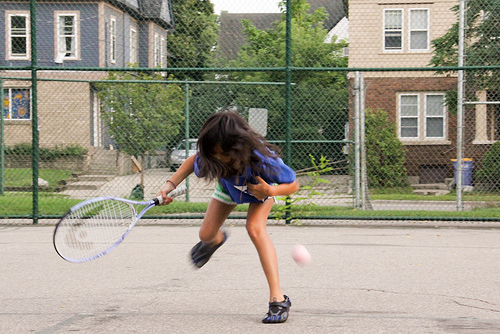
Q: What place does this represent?
A: It represents the pavement.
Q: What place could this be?
A: It is a pavement.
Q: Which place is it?
A: It is a pavement.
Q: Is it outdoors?
A: Yes, it is outdoors.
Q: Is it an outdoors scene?
A: Yes, it is outdoors.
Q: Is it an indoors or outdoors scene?
A: It is outdoors.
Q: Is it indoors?
A: No, it is outdoors.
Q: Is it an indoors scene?
A: No, it is outdoors.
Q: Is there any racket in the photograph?
A: Yes, there is a racket.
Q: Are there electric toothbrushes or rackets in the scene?
A: Yes, there is a racket.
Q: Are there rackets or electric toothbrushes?
A: Yes, there is a racket.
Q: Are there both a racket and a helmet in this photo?
A: No, there is a racket but no helmets.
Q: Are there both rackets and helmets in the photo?
A: No, there is a racket but no helmets.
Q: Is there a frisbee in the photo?
A: No, there are no frisbees.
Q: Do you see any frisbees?
A: No, there are no frisbees.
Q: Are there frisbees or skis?
A: No, there are no frisbees or skis.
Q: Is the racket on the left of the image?
A: Yes, the racket is on the left of the image.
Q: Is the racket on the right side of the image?
A: No, the racket is on the left of the image.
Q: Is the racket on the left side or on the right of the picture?
A: The racket is on the left of the image.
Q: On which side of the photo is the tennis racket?
A: The tennis racket is on the left of the image.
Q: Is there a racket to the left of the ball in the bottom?
A: Yes, there is a racket to the left of the ball.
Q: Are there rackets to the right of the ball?
A: No, the racket is to the left of the ball.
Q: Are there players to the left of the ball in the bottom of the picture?
A: No, there is a racket to the left of the ball.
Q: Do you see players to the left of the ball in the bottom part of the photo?
A: No, there is a racket to the left of the ball.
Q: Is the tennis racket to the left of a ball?
A: Yes, the tennis racket is to the left of a ball.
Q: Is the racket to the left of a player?
A: No, the racket is to the left of a ball.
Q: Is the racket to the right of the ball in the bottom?
A: No, the racket is to the left of the ball.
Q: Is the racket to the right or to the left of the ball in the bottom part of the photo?
A: The racket is to the left of the ball.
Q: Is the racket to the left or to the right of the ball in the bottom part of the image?
A: The racket is to the left of the ball.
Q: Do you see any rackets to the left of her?
A: Yes, there is a racket to the left of the girl.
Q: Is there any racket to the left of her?
A: Yes, there is a racket to the left of the girl.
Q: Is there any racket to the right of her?
A: No, the racket is to the left of the girl.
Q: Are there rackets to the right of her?
A: No, the racket is to the left of the girl.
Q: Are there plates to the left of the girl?
A: No, there is a racket to the left of the girl.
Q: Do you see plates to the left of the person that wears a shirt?
A: No, there is a racket to the left of the girl.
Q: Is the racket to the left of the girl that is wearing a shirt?
A: Yes, the racket is to the left of the girl.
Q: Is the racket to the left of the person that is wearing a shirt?
A: Yes, the racket is to the left of the girl.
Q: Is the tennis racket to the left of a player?
A: No, the tennis racket is to the left of the girl.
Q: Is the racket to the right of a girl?
A: No, the racket is to the left of a girl.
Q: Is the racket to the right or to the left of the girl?
A: The racket is to the left of the girl.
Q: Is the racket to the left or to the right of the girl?
A: The racket is to the left of the girl.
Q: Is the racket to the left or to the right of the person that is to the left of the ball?
A: The racket is to the left of the girl.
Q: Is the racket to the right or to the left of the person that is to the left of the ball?
A: The racket is to the left of the girl.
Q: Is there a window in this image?
A: Yes, there is a window.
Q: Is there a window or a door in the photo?
A: Yes, there is a window.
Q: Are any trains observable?
A: No, there are no trains.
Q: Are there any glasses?
A: No, there are no glasses.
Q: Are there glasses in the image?
A: No, there are no glasses.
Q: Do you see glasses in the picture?
A: No, there are no glasses.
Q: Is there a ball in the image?
A: Yes, there is a ball.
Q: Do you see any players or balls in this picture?
A: Yes, there is a ball.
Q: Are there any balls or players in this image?
A: Yes, there is a ball.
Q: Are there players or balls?
A: Yes, there is a ball.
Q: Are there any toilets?
A: No, there are no toilets.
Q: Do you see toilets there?
A: No, there are no toilets.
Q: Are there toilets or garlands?
A: No, there are no toilets or garlands.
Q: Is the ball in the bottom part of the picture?
A: Yes, the ball is in the bottom of the image.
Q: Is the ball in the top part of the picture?
A: No, the ball is in the bottom of the image.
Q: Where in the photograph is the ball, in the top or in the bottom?
A: The ball is in the bottom of the image.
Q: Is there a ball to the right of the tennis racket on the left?
A: Yes, there is a ball to the right of the racket.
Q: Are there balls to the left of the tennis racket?
A: No, the ball is to the right of the tennis racket.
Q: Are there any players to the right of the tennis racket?
A: No, there is a ball to the right of the tennis racket.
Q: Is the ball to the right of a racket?
A: Yes, the ball is to the right of a racket.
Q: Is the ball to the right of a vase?
A: No, the ball is to the right of a racket.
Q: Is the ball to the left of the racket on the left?
A: No, the ball is to the right of the racket.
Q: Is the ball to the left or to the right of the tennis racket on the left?
A: The ball is to the right of the racket.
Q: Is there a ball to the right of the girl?
A: Yes, there is a ball to the right of the girl.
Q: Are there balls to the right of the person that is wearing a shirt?
A: Yes, there is a ball to the right of the girl.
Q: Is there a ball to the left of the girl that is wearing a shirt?
A: No, the ball is to the right of the girl.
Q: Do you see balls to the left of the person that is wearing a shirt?
A: No, the ball is to the right of the girl.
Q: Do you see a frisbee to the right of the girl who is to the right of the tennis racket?
A: No, there is a ball to the right of the girl.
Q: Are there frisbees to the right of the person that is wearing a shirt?
A: No, there is a ball to the right of the girl.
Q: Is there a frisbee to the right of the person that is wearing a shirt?
A: No, there is a ball to the right of the girl.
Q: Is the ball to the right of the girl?
A: Yes, the ball is to the right of the girl.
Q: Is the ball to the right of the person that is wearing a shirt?
A: Yes, the ball is to the right of the girl.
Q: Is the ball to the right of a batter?
A: No, the ball is to the right of the girl.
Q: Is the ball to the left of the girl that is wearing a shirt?
A: No, the ball is to the right of the girl.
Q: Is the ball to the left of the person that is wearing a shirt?
A: No, the ball is to the right of the girl.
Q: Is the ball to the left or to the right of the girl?
A: The ball is to the right of the girl.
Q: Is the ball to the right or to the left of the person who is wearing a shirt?
A: The ball is to the right of the girl.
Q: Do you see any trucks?
A: No, there are no trucks.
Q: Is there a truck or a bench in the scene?
A: No, there are no trucks or benches.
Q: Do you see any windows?
A: Yes, there is a window.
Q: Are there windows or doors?
A: Yes, there is a window.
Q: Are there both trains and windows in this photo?
A: No, there is a window but no trains.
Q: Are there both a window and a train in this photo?
A: No, there is a window but no trains.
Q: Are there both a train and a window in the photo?
A: No, there is a window but no trains.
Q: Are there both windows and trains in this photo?
A: No, there is a window but no trains.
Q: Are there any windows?
A: Yes, there are windows.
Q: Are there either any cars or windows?
A: Yes, there are windows.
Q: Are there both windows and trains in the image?
A: No, there are windows but no trains.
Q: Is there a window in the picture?
A: Yes, there is a window.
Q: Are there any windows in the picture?
A: Yes, there is a window.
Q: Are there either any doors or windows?
A: Yes, there is a window.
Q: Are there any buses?
A: No, there are no buses.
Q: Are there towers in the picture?
A: No, there are no towers.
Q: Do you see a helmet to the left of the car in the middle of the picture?
A: No, there is a house to the left of the car.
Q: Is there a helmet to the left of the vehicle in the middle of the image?
A: No, there is a house to the left of the car.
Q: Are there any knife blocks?
A: No, there are no knife blocks.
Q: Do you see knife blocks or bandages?
A: No, there are no knife blocks or bandages.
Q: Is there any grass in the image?
A: Yes, there is grass.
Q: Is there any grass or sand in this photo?
A: Yes, there is grass.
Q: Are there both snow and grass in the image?
A: No, there is grass but no snow.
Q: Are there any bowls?
A: No, there are no bowls.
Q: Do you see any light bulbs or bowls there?
A: No, there are no bowls or light bulbs.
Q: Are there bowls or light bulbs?
A: No, there are no bowls or light bulbs.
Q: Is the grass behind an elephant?
A: No, the grass is behind the fence.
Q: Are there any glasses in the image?
A: No, there are no glasses.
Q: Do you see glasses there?
A: No, there are no glasses.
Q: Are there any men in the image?
A: No, there are no men.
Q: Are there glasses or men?
A: No, there are no men or glasses.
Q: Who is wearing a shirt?
A: The girl is wearing a shirt.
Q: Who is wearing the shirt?
A: The girl is wearing a shirt.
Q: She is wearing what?
A: The girl is wearing a shirt.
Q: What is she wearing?
A: The girl is wearing a shirt.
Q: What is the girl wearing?
A: The girl is wearing a shirt.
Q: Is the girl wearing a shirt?
A: Yes, the girl is wearing a shirt.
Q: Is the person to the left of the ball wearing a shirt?
A: Yes, the girl is wearing a shirt.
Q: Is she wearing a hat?
A: No, the girl is wearing a shirt.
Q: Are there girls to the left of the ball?
A: Yes, there is a girl to the left of the ball.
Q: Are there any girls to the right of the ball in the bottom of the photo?
A: No, the girl is to the left of the ball.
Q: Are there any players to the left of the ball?
A: No, there is a girl to the left of the ball.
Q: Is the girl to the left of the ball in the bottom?
A: Yes, the girl is to the left of the ball.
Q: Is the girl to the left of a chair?
A: No, the girl is to the left of the ball.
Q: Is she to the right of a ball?
A: No, the girl is to the left of a ball.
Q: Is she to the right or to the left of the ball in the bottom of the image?
A: The girl is to the left of the ball.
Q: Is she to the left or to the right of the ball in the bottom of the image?
A: The girl is to the left of the ball.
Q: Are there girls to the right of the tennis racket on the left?
A: Yes, there is a girl to the right of the tennis racket.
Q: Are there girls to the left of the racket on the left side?
A: No, the girl is to the right of the racket.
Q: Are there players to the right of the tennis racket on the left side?
A: No, there is a girl to the right of the tennis racket.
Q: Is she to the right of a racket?
A: Yes, the girl is to the right of a racket.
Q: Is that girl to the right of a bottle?
A: No, the girl is to the right of a racket.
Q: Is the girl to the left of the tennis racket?
A: No, the girl is to the right of the tennis racket.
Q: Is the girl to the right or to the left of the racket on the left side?
A: The girl is to the right of the racket.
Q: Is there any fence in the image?
A: Yes, there is a fence.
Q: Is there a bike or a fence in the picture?
A: Yes, there is a fence.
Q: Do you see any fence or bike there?
A: Yes, there is a fence.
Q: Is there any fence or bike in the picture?
A: Yes, there is a fence.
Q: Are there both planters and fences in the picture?
A: No, there is a fence but no planters.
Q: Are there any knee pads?
A: No, there are no knee pads.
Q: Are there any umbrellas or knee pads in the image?
A: No, there are no knee pads or umbrellas.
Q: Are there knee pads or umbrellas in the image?
A: No, there are no knee pads or umbrellas.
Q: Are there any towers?
A: No, there are no towers.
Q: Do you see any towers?
A: No, there are no towers.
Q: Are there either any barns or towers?
A: No, there are no towers or barns.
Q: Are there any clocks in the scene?
A: No, there are no clocks.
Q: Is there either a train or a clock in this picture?
A: No, there are no clocks or trains.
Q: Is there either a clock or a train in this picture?
A: No, there are no clocks or trains.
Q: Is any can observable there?
A: Yes, there is a can.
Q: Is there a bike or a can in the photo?
A: Yes, there is a can.